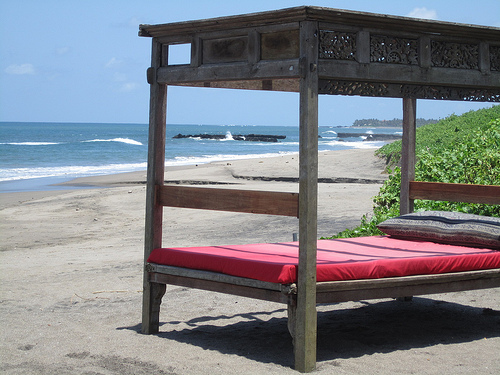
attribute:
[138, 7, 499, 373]
bed — wooden, wood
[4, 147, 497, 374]
beach — tan, sandy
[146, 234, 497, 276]
mattress — red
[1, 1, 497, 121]
sky — blue, clear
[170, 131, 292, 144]
rocks — black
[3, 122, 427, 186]
ocean — blue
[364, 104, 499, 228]
hill — green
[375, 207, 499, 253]
pillow — gray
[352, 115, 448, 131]
tree line — far